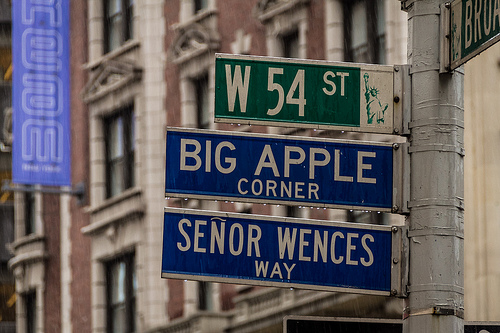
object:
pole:
[401, 0, 462, 332]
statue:
[359, 72, 387, 124]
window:
[101, 109, 126, 201]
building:
[0, 0, 499, 332]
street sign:
[211, 53, 402, 134]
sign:
[160, 205, 407, 301]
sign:
[165, 125, 409, 214]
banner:
[10, 0, 71, 186]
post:
[134, 0, 170, 332]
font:
[174, 218, 262, 258]